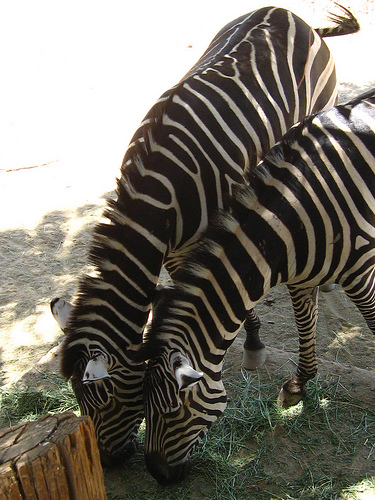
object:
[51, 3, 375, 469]
zebra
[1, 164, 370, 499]
ground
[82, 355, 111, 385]
ear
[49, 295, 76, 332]
ear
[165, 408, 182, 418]
eye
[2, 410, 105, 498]
wood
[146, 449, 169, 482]
nose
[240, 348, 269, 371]
hoof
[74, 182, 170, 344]
neck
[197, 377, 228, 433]
jaw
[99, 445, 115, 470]
nose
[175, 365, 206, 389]
ear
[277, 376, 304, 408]
hoof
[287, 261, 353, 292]
stomach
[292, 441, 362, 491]
hay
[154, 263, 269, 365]
neck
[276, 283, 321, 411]
leg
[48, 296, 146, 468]
head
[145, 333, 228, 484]
head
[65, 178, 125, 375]
mane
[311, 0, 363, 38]
tail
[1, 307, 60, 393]
sunlight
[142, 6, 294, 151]
back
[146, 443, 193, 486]
snout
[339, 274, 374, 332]
leg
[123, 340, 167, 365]
ear